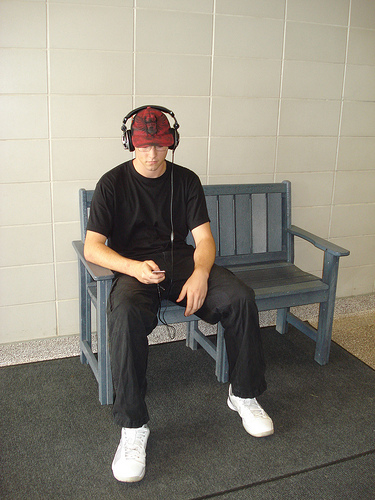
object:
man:
[80, 104, 276, 484]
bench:
[73, 180, 350, 408]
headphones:
[120, 104, 181, 149]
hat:
[131, 107, 176, 147]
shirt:
[84, 156, 208, 252]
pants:
[108, 250, 268, 425]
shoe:
[108, 421, 155, 485]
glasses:
[137, 147, 166, 153]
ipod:
[152, 268, 166, 276]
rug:
[5, 320, 375, 499]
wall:
[2, 0, 373, 328]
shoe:
[223, 382, 279, 442]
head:
[128, 107, 173, 171]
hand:
[177, 279, 209, 317]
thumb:
[177, 284, 187, 305]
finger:
[192, 293, 198, 313]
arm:
[186, 199, 215, 276]